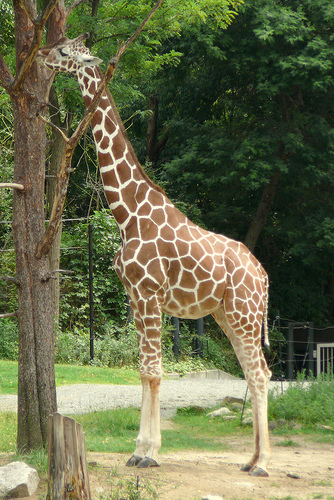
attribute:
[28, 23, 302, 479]
giraffe — yellow and brown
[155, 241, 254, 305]
spots — brown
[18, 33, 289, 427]
giraffe — yellow, brown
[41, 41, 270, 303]
giraffe — yellow and brown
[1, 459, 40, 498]
rock — small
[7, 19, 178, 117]
giraffe eating — yellow and brown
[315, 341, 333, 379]
fence — metal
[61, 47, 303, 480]
giraffe — yellow and brown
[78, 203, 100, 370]
pole — black, metal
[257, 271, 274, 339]
tail — black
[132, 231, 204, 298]
giraffe — yellow and brown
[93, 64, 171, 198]
mane — brown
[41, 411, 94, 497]
tree trunk — brown